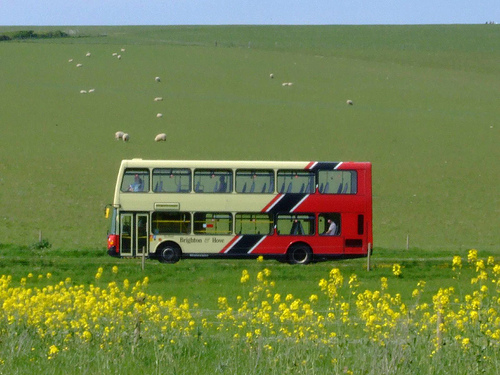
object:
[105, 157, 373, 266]
bus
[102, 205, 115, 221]
mirror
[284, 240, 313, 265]
back wheel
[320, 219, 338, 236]
man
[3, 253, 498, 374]
flowers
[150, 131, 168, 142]
sheep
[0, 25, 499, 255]
field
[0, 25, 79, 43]
bushes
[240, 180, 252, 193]
chair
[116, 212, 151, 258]
door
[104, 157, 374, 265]
stripe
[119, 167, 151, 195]
window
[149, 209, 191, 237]
window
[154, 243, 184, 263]
front wheel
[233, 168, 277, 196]
top window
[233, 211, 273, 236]
bottom window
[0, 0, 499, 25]
sky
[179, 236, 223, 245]
letters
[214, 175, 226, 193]
passenger